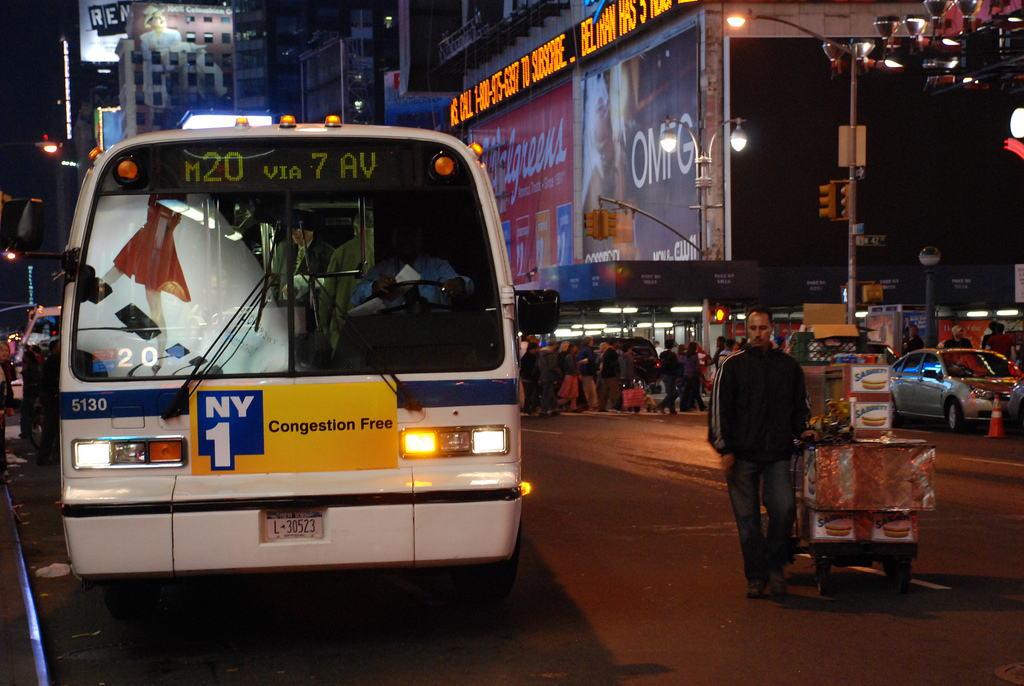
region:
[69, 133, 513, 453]
a view of glass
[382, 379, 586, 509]
a view of lights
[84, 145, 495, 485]
front glass of bus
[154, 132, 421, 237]
distination display of bus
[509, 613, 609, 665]
shadow on the road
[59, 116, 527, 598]
white bus with yellow sign on front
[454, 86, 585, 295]
red billboard with white lettering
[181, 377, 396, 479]
yellow sign with blue, white, and black lettering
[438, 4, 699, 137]
scrolling marquee sign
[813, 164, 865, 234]
yellow traffic light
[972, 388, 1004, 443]
orange traffic cone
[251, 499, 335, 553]
New York State license plate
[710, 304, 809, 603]
man wearing blue jeans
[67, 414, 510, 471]
headlights on a bus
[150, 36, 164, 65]
a window on a building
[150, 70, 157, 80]
a window on a building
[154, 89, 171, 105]
a window on a building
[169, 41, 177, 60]
a window on a building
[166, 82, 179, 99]
a window on a building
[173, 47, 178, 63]
a window on a building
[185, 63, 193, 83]
a window on a building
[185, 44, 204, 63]
a window on a building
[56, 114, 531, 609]
A city bus.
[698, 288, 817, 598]
A man pushing a cart full of supplies.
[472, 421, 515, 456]
A left front bus headlight.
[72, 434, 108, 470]
A right front headlight.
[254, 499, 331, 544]
A license plate on a bus.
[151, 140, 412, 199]
A marque on a bus.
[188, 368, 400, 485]
A sign on the front of a bus.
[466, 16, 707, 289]
A giant sign on a building.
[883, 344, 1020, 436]
A car parked behind a cone.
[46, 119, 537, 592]
a public transportation bus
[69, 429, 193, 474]
headlight on a bus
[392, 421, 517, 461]
headlight on a bus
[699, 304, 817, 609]
man wearing black jacket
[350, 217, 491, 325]
bus driver driving a bus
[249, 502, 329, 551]
license plate on a bus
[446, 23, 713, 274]
a couple advertising billboard ads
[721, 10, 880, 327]
a city street light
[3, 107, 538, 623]
Front of a bus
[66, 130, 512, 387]
Wide glass windshield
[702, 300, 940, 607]
Man walking next to his food cart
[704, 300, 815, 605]
Man in blue jeans walking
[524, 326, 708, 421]
People crossing the pedestrian lane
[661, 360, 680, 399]
a person standing outside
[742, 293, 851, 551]
a person standing outside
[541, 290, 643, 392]
a person standing outside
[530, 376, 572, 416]
a person standing outside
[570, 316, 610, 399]
a person standing outside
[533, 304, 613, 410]
a person standing outside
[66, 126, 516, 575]
a large white bus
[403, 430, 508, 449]
the headlight on the bus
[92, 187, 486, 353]
the windshield on the bus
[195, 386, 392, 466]
a sign on the bus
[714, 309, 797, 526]
a man in a black jacket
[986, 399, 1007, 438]
an orange traffic cone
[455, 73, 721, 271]
a large billboard sign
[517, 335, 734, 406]
people walking on the street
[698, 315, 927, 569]
a man pulling a cart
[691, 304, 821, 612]
man pulling a cart